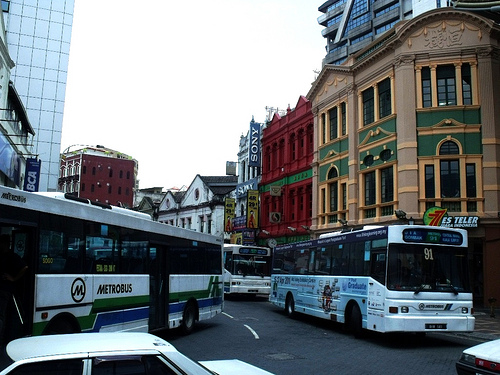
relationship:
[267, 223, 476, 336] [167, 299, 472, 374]
bus on street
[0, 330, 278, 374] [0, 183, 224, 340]
car next to bus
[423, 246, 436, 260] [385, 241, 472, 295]
number 91 on windshield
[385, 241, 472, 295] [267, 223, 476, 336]
windshield on bus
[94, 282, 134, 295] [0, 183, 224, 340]
metrobus on bus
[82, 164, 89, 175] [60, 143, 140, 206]
window on building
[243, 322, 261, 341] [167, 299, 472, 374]
line on street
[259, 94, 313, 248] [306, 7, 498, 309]
building next to building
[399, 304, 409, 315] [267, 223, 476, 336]
headlight on bus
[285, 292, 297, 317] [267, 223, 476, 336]
wheel on bus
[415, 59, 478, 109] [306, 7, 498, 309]
window on building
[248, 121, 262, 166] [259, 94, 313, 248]
sign on building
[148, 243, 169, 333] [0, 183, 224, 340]
door on bus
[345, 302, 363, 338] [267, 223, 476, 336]
wheel on bus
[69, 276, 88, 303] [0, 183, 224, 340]
logo on bus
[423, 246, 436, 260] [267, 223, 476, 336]
number 91 on bus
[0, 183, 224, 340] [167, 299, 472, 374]
bus on street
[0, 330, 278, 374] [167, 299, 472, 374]
car on street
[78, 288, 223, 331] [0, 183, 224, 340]
stripes on bus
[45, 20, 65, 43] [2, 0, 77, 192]
window on building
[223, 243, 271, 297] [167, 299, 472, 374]
bus on street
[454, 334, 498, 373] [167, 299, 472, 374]
car on street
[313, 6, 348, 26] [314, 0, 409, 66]
balcony on building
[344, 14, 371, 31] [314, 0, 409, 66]
windows on building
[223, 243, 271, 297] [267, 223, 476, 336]
bus driving behind bus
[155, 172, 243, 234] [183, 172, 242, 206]
building has roof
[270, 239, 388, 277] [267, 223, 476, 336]
windows on bus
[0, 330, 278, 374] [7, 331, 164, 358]
car has roof